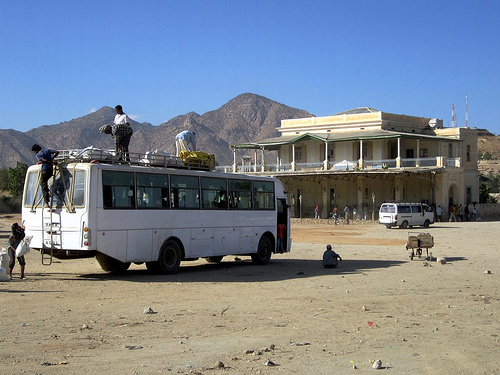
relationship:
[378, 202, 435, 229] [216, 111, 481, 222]
minivan outside building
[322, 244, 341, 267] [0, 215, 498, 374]
person on ground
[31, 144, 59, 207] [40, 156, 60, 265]
man standing on ladder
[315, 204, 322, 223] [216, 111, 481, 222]
person standing outside building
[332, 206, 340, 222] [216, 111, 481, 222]
person standing outside building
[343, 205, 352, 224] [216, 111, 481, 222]
person standing outside building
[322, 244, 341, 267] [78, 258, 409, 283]
person in shadow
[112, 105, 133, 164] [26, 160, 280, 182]
man standing on roof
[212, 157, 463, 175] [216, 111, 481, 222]
balcony on building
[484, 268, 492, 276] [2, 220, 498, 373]
rock on road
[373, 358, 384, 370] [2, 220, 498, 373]
rock on road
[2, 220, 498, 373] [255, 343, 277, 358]
road with rocks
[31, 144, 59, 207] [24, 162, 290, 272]
man standing on bus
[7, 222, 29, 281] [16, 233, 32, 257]
person handing package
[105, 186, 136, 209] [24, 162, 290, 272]
window in bus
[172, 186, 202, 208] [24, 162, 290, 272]
window in bus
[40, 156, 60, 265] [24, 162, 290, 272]
ladder on bus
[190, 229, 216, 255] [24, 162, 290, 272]
unit on bus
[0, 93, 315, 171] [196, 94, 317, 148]
line of mountain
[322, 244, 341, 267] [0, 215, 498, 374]
person sitting on ground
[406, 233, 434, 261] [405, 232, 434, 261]
buggy with buggy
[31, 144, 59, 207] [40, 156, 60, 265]
man on ladder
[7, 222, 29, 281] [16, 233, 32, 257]
person holding package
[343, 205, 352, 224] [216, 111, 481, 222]
person in front of building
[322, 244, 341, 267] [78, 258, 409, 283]
person sitting in shadow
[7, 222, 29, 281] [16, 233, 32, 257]
person passing package